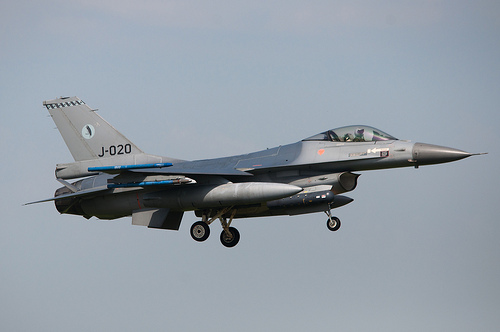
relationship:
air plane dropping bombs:
[21, 96, 488, 247] [135, 168, 205, 197]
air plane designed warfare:
[21, 96, 488, 247] [145, 147, 393, 238]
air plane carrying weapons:
[21, 96, 488, 247] [213, 179, 312, 216]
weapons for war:
[213, 179, 312, 216] [210, 172, 308, 208]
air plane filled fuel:
[21, 96, 488, 247] [137, 182, 347, 220]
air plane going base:
[21, 96, 488, 247] [356, 292, 448, 326]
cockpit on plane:
[325, 120, 394, 155] [79, 104, 355, 259]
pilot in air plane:
[352, 125, 363, 140] [18, 93, 488, 246]